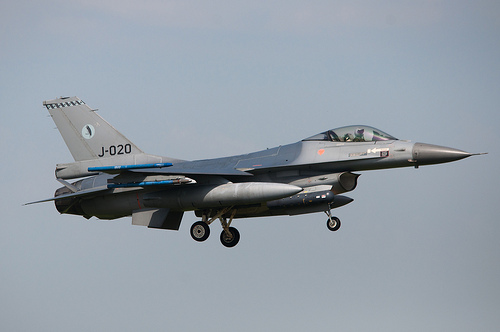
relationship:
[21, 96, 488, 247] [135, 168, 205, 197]
air plane dropping bombs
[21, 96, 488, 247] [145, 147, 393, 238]
air plane designed warfare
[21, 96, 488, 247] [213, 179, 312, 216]
air plane carrying weapons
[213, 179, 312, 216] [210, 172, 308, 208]
weapons for war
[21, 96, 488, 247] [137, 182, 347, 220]
air plane filled fuel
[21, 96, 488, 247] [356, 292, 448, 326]
air plane going base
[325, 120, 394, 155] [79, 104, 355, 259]
cockpit on plane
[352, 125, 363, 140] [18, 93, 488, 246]
pilot in air plane